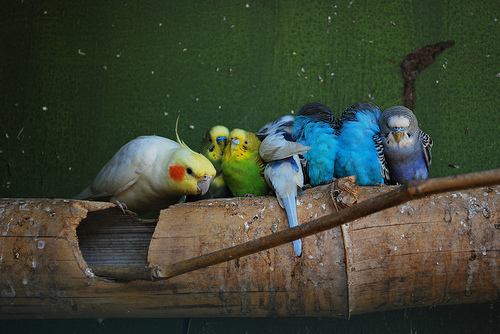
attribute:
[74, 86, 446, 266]
birds — colorful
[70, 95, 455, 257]
birds — colorful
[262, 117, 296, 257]
feathers — blue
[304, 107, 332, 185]
feathers — blue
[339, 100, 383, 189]
feathers — blue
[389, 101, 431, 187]
feathers — blue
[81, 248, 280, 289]
twig — sticking out of a hole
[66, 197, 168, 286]
hole — in the log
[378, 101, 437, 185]
birds — colorful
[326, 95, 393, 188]
birds — colorful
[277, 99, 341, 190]
birds — colorful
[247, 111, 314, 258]
birds — colorful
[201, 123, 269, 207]
birds — colorful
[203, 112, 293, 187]
bird — yellow, green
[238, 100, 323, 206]
bird — blue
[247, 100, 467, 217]
bird — blue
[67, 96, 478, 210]
bird — sitting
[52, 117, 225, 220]
bird — large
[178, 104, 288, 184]
birds — yellow, green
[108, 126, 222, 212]
bird — large, looking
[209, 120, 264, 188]
lovebirds — green, yellow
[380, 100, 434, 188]
bird — fluffy, white, grey, blue, colorful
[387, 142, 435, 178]
body — blue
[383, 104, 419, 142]
head — gray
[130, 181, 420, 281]
crack — long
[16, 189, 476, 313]
perch — hollow, wooden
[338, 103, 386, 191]
bird — bright blue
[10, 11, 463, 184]
fabric — dark green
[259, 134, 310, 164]
wing — pale blue, stretched out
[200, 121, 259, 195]
birds — green, yellow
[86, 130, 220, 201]
bird — larger, white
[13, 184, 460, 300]
log — large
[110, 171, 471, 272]
stick — small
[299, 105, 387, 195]
birds — similar, blue, together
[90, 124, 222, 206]
bird — white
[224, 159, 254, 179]
chest — wide, green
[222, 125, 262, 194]
bird — small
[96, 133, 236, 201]
bird — white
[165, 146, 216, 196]
head — yellow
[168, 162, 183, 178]
spot — red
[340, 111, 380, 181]
bird — bright blue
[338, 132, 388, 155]
wings — black, white, striped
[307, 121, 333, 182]
bird — bright blue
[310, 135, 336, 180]
wings — black, white, striped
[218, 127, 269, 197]
bird — colorful, green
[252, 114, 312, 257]
bird — colorful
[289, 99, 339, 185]
bird — colorful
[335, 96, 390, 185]
bird — colorful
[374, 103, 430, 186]
bird — blue, grey, black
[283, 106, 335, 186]
bird — blue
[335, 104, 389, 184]
bird — blue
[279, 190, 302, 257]
bird tail — blue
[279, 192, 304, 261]
tail — blue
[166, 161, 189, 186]
spot — orange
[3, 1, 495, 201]
wall — green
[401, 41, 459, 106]
spot — brown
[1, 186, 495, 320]
branch — wooden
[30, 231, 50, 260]
spot — white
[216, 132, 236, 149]
spot — blue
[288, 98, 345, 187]
bird — blue